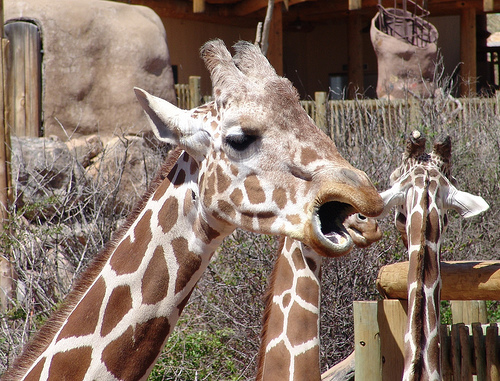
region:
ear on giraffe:
[140, 95, 195, 156]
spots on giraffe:
[118, 234, 182, 294]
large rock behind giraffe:
[46, 7, 158, 74]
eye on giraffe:
[217, 127, 258, 159]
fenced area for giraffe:
[347, 102, 405, 134]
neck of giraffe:
[263, 252, 316, 374]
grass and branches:
[178, 330, 246, 379]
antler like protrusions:
[199, 41, 269, 82]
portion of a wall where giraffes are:
[293, 40, 343, 70]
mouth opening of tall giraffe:
[314, 182, 364, 251]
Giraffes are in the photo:
[40, 32, 457, 373]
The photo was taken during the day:
[0, 35, 470, 376]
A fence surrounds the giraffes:
[52, 80, 493, 260]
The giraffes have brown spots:
[42, 88, 467, 378]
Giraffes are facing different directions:
[53, 31, 465, 378]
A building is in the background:
[130, 6, 477, 292]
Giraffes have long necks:
[65, 35, 480, 375]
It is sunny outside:
[32, 16, 463, 338]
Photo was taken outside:
[3, 42, 433, 368]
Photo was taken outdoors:
[45, 36, 467, 378]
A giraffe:
[111, 34, 395, 301]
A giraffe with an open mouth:
[109, 39, 389, 276]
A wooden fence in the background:
[307, 81, 425, 145]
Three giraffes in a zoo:
[64, 15, 478, 344]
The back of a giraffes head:
[381, 125, 469, 296]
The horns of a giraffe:
[186, 31, 281, 88]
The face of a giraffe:
[227, 92, 374, 266]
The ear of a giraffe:
[112, 86, 213, 169]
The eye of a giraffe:
[214, 121, 272, 161]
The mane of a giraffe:
[257, 238, 277, 379]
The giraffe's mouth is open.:
[266, 160, 388, 259]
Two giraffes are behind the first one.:
[237, 120, 488, 379]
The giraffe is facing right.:
[131, 37, 388, 262]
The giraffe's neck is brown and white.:
[0, 169, 226, 379]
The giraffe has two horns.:
[191, 28, 286, 100]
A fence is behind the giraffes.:
[340, 255, 498, 377]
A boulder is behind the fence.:
[0, 2, 189, 145]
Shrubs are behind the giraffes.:
[137, 303, 244, 379]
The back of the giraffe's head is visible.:
[357, 119, 490, 249]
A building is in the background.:
[162, 1, 497, 118]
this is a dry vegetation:
[18, 131, 88, 251]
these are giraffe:
[94, 100, 459, 348]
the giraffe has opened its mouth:
[119, 35, 391, 265]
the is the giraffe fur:
[81, 207, 170, 332]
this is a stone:
[0, 0, 180, 132]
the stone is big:
[9, 0, 179, 93]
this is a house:
[174, 0, 498, 56]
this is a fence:
[349, 263, 499, 376]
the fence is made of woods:
[341, 259, 498, 376]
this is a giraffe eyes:
[206, 117, 273, 172]